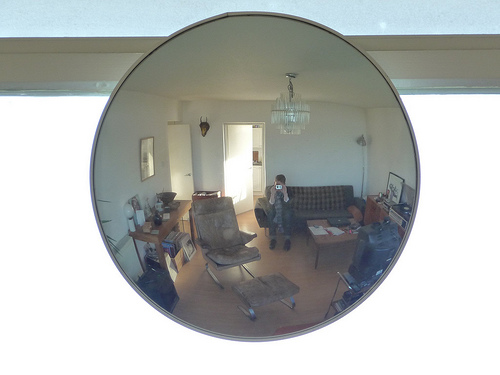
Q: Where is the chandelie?
A: Hanging from the ceiling.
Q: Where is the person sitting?
A: On the sofa.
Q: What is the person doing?
A: Taking a photo.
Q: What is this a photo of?
A: A reflection in a round mirror.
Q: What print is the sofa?
A: Plaid.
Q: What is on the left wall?
A: A picture.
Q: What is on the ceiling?
A: Chandelier.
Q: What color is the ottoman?
A: Brown.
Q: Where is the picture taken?
A: Living room.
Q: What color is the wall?
A: White.